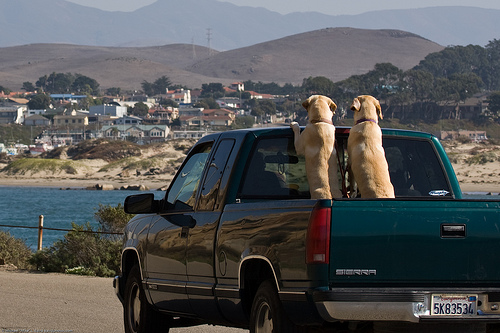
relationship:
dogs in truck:
[298, 97, 376, 204] [136, 116, 493, 330]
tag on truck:
[433, 288, 482, 320] [136, 116, 493, 330]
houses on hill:
[18, 80, 276, 142] [138, 62, 485, 144]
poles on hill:
[189, 33, 221, 59] [138, 62, 485, 144]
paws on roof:
[283, 118, 308, 135] [202, 120, 431, 146]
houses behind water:
[18, 80, 276, 142] [3, 171, 126, 229]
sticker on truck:
[427, 191, 456, 207] [136, 116, 493, 330]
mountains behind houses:
[10, 3, 496, 105] [18, 80, 276, 142]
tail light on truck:
[305, 206, 330, 264] [136, 116, 493, 330]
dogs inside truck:
[298, 97, 376, 204] [136, 116, 493, 330]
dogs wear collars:
[298, 97, 376, 204] [307, 116, 367, 138]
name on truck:
[328, 262, 382, 280] [136, 116, 493, 330]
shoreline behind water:
[1, 172, 175, 189] [3, 171, 126, 229]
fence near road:
[2, 209, 134, 266] [6, 277, 101, 328]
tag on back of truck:
[433, 288, 482, 320] [136, 116, 493, 330]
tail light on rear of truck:
[309, 203, 345, 275] [136, 116, 493, 330]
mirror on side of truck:
[122, 191, 162, 226] [136, 116, 493, 330]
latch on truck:
[436, 224, 475, 241] [136, 116, 493, 330]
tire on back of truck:
[225, 277, 293, 329] [136, 116, 493, 330]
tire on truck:
[103, 241, 173, 315] [136, 116, 493, 330]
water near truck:
[3, 171, 126, 229] [136, 116, 493, 330]